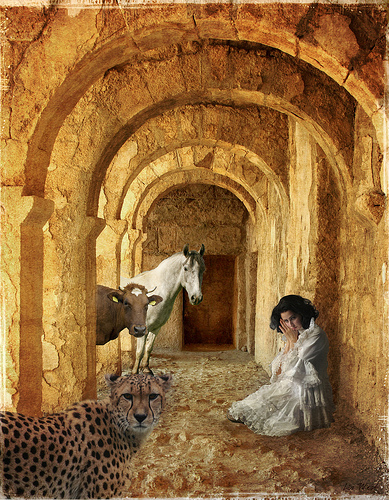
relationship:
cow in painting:
[93, 282, 162, 348] [2, 2, 385, 498]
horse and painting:
[132, 242, 206, 374] [2, 2, 385, 498]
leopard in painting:
[6, 369, 169, 500] [2, 2, 385, 498]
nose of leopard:
[133, 412, 148, 421] [6, 369, 169, 500]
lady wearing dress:
[222, 297, 332, 440] [230, 323, 335, 439]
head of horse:
[177, 242, 206, 306] [132, 242, 206, 374]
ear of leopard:
[97, 369, 122, 389] [6, 369, 169, 500]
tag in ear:
[111, 296, 119, 304] [106, 290, 124, 309]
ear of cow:
[106, 290, 124, 309] [93, 282, 162, 348]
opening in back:
[178, 249, 238, 353] [140, 180, 253, 364]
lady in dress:
[222, 297, 332, 440] [230, 323, 335, 439]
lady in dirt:
[222, 297, 332, 440] [102, 339, 375, 493]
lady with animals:
[222, 297, 332, 440] [7, 240, 211, 499]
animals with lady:
[7, 240, 211, 499] [222, 297, 332, 440]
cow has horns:
[93, 282, 162, 348] [117, 281, 157, 295]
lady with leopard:
[222, 297, 332, 440] [6, 369, 169, 500]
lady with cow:
[222, 297, 332, 440] [93, 282, 162, 348]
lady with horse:
[222, 297, 332, 440] [132, 242, 206, 374]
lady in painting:
[222, 297, 332, 440] [2, 2, 385, 498]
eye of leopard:
[120, 392, 134, 404] [6, 369, 169, 500]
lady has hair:
[222, 297, 332, 440] [270, 294, 320, 333]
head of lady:
[268, 293, 323, 332] [222, 297, 332, 440]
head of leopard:
[101, 364, 175, 432] [6, 369, 169, 500]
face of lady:
[278, 310, 303, 333] [222, 297, 332, 440]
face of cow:
[278, 310, 303, 333] [93, 282, 162, 348]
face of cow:
[120, 296, 147, 333] [93, 282, 162, 348]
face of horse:
[181, 261, 204, 303] [132, 242, 206, 374]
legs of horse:
[124, 330, 156, 378] [132, 242, 206, 374]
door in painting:
[179, 256, 239, 357] [2, 2, 385, 498]